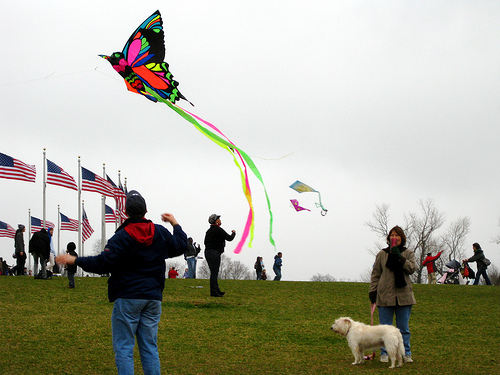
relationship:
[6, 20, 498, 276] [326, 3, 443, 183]
clouds in skies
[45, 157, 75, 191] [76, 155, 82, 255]
flag on top of pole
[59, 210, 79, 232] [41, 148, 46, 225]
flag on top of pole